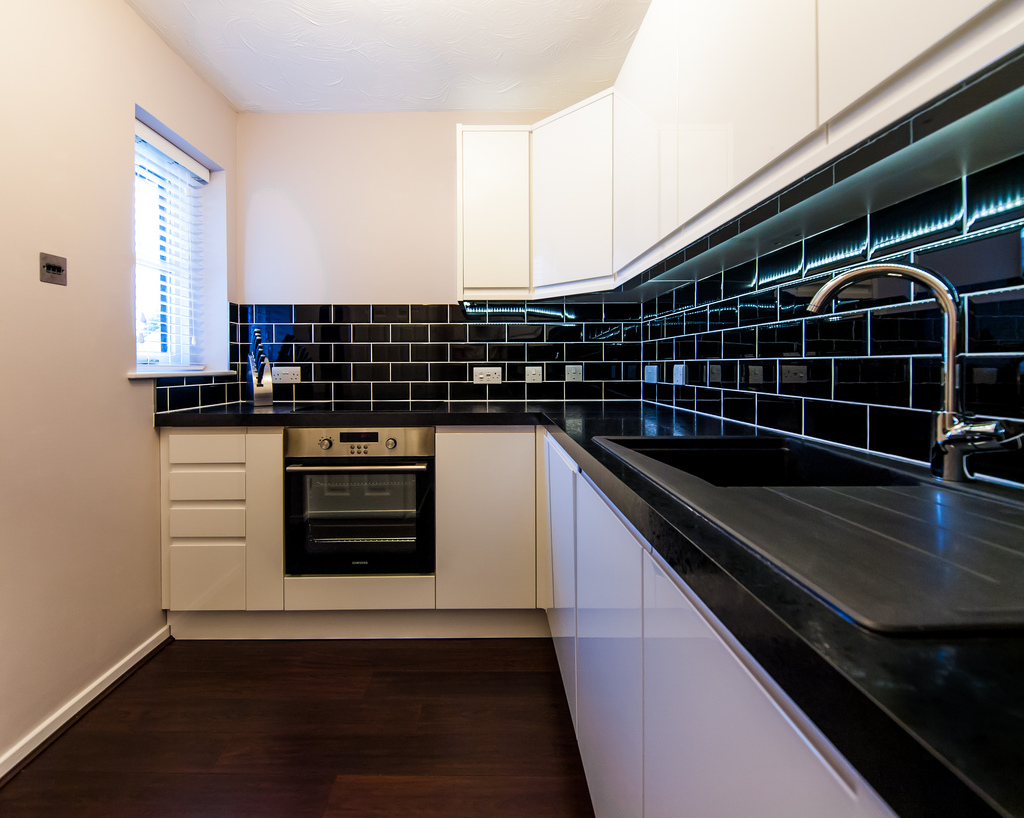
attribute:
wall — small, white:
[245, 108, 455, 306]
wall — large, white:
[5, 0, 243, 773]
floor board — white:
[7, 621, 173, 767]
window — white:
[130, 133, 214, 362]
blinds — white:
[138, 144, 200, 340]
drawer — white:
[157, 438, 247, 543]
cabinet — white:
[427, 428, 532, 610]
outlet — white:
[469, 364, 502, 387]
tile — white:
[561, 361, 582, 382]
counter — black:
[163, 389, 1015, 816]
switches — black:
[42, 260, 66, 273]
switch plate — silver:
[35, 248, 73, 284]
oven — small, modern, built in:
[277, 421, 433, 578]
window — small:
[118, 111, 245, 380]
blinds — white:
[133, 150, 207, 356]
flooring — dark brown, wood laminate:
[11, 618, 607, 805]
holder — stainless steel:
[244, 354, 277, 411]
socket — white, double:
[266, 367, 301, 387]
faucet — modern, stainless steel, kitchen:
[800, 251, 1010, 473]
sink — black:
[602, 387, 926, 495]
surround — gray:
[563, 389, 1010, 649]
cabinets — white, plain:
[450, 10, 1010, 328]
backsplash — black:
[146, 61, 1014, 492]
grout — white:
[152, 57, 1010, 495]